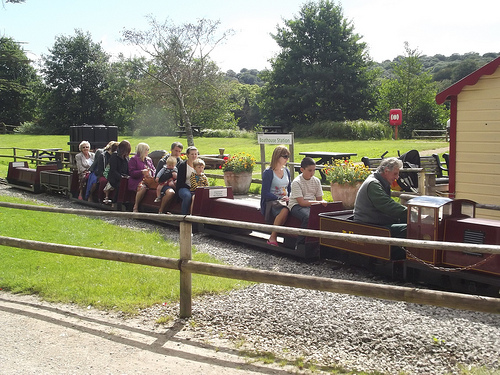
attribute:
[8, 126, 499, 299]
train — miniature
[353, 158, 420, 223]
man — old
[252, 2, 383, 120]
tree — big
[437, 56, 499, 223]
building — yellow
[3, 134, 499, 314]
grass — green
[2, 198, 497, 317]
fence — wooden, wood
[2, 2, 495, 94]
sky — blue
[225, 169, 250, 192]
planter — concrete